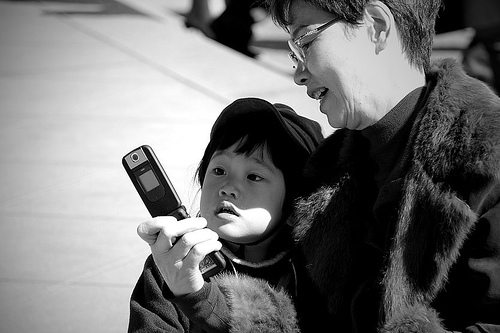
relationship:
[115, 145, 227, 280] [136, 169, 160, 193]
cellphone has screen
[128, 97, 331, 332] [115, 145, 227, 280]
girl looking at cellphone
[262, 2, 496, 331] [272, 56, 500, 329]
lady wearing coat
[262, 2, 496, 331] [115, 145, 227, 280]
lady holds cellphone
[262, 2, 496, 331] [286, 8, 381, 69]
lady wearing glasses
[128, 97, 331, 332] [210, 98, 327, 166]
girl wearing hat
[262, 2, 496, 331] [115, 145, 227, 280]
lady looking at cellphone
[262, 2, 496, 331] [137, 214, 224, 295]
lady has hand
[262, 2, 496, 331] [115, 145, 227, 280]
lady holding cellphone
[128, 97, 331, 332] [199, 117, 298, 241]
girl has face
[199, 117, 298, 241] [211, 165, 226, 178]
face has dark eye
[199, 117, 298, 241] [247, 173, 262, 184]
face has dark eye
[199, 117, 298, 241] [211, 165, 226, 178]
face had dark eye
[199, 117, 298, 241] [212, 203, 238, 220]
face has mouth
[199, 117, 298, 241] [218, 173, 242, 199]
face has nose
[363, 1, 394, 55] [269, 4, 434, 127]
ear on head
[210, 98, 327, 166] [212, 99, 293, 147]
hat has brim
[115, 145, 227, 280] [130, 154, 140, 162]
cellphone has lens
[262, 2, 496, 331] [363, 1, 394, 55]
lady has ear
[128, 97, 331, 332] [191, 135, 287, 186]
girl has hair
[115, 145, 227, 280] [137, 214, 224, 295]
cellphone in hand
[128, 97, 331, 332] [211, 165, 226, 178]
girl has dark eye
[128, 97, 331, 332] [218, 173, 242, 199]
girl has nose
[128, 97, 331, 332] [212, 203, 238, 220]
girl has mouth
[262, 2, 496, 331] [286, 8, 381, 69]
lady has glasses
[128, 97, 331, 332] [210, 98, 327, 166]
girl has hat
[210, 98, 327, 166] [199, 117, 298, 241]
hat on head